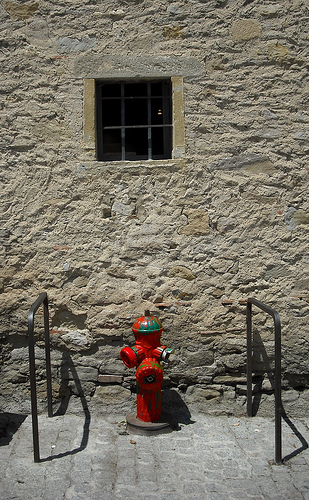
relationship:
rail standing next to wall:
[243, 296, 284, 463] [1, 1, 299, 416]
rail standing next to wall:
[25, 290, 54, 462] [1, 1, 299, 416]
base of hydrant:
[115, 409, 189, 452] [100, 304, 177, 406]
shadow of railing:
[57, 353, 109, 457] [18, 287, 55, 394]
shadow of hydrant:
[138, 368, 197, 432] [118, 310, 182, 411]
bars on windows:
[97, 114, 188, 139] [91, 65, 183, 207]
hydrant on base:
[119, 307, 177, 424] [119, 398, 176, 436]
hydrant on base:
[99, 305, 204, 416] [114, 401, 201, 452]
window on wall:
[75, 56, 204, 165] [5, 28, 276, 280]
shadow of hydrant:
[131, 380, 213, 439] [116, 316, 208, 422]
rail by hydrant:
[246, 297, 283, 464] [111, 300, 208, 419]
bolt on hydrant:
[134, 307, 162, 324] [110, 310, 181, 427]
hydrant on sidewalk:
[119, 307, 177, 424] [19, 407, 307, 492]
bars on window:
[105, 91, 162, 144] [77, 72, 209, 182]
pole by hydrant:
[209, 303, 291, 417] [115, 313, 197, 409]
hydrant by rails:
[119, 307, 177, 424] [200, 291, 298, 443]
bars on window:
[93, 75, 175, 159] [88, 74, 175, 158]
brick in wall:
[220, 352, 247, 375] [1, 1, 299, 416]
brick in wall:
[97, 373, 123, 384] [1, 1, 299, 416]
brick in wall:
[63, 380, 96, 394] [1, 1, 299, 416]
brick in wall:
[60, 364, 93, 381] [1, 1, 299, 416]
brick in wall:
[177, 383, 188, 392] [1, 1, 299, 416]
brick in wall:
[99, 371, 124, 381] [1, 1, 299, 416]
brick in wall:
[217, 365, 253, 385] [1, 1, 299, 416]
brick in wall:
[235, 378, 257, 393] [1, 1, 299, 416]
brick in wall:
[57, 364, 98, 383] [1, 1, 299, 416]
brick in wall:
[170, 371, 194, 387] [1, 1, 299, 416]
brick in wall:
[10, 372, 25, 383] [1, 1, 299, 416]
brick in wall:
[93, 362, 132, 377] [1, 1, 299, 416]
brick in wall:
[214, 352, 248, 368] [1, 1, 299, 416]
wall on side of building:
[0, 0, 309, 417] [3, 0, 304, 391]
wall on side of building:
[19, 192, 304, 381] [0, 5, 307, 421]